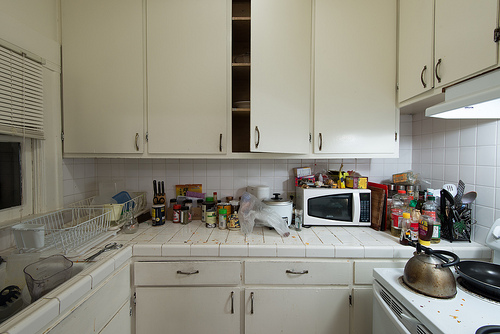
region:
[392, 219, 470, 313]
teapot on white stove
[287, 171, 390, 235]
white microwave on counter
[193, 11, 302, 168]
cabinet door partially opened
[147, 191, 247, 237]
spice jars on counter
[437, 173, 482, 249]
utensil holder beside stove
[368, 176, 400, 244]
cutting board beside microwave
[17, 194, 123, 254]
empty dish drainer beside sink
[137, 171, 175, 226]
three knives in knife block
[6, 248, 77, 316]
dirty dishes in sink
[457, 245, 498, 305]
frying pan on stove top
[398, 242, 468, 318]
Silver tea kettle with black handle.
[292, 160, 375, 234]
White and black microwave with lots of stuff on top.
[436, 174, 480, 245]
Utensils in a black caddy.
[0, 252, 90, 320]
Dirty dishes in sink.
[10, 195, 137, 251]
White dish dryer on counter.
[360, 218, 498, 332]
White stove with tea kettle and frying pan.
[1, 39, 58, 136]
Mini blinds on window.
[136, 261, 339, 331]
White cupboards with silver handles.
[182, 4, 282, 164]
White cupboard door half open.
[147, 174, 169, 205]
Set of knives in knife block.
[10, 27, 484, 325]
a messy kitchen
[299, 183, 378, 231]
a small microwave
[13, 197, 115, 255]
an empty dish rack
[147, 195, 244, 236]
a number of spices on the counter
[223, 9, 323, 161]
an open cabinet door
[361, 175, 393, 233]
a couple cutting board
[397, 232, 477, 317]
a tea kettle on the stove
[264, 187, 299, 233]
a white rice cooker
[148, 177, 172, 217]
a knife set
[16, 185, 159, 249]
two plastic dish racks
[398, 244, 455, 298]
stainless steel tea kettle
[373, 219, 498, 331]
white enamel stove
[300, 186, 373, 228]
black and white microwave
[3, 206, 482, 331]
white tile counter top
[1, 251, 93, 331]
kitchen sink full of dirty dishes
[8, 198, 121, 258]
white plastic dish rack next to sink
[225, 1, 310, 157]
open cupboard door is painted white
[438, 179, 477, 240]
container full of utensils on the counter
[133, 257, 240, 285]
painted wood drawer with metal handle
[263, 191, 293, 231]
white rice cooker on counter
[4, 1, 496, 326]
fully white kitchen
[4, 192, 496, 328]
white tile counter tops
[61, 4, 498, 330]
white wooden cabinets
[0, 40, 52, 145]
white slatted window blind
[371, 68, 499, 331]
light lit above stove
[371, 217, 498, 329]
silver kettle on stove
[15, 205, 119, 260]
white dish rack next to sink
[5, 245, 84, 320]
sink full of dishes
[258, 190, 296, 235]
white pressure cooker near microwave